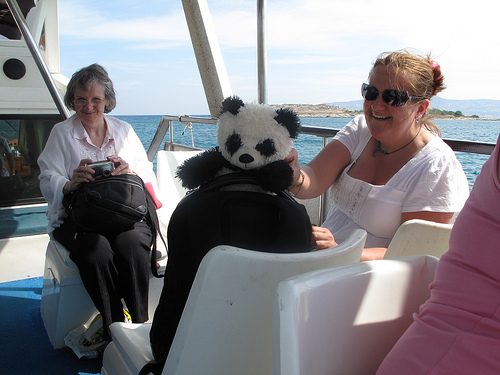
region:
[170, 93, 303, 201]
a panda plush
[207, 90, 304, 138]
ears of panda plush are black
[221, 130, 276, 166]
eyes and nose of panda plush are black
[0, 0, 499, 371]
women in a boat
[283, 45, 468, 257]
woman combs with a bun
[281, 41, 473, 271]
woman has white top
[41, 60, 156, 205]
woman has gray hair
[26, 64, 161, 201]
woman holds a camera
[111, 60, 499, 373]
people sits on white chairs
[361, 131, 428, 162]
necklace on neck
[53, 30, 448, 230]
two women on boat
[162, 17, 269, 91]
white rail on boat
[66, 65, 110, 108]
woman has grey hair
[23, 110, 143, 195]
woman has white shirt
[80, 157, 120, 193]
woman is holding camera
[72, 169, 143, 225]
woman is holding black bag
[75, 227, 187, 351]
woman has black pants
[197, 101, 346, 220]
woman holds panda doll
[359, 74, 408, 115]
woman is wearing sunglasses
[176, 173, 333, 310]
panda on black luggage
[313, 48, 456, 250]
a woman wearing white on a boat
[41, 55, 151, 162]
a woman wearing white on a boat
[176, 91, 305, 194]
a stuffed panda bear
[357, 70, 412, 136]
the face of a woman wearing sunglasses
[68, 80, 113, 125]
the face of a woman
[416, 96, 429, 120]
the ear of a woman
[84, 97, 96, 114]
the nose of a woman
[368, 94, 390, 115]
the nose of a woman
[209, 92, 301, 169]
the head of a stuffed panda's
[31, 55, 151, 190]
a woman holding a camera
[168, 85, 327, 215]
A panda bear on a woman's lap.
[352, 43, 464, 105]
A woman with brown hair.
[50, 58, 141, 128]
a woman with gray hair.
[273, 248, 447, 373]
a white seat on a boat.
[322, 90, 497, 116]
a small mountain range.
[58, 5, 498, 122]
a cloud filled blue sky.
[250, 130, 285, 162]
A black panda bear eye.;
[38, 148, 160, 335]
a woman holding a camera.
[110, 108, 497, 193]
A large body of water.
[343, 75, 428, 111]
a pair of black sun glasses.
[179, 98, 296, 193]
a soft panda toy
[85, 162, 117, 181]
a silver camera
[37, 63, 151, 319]
a woman holding a camera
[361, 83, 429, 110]
a pair of black sunglasses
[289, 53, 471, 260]
a woman wearing black sunglasses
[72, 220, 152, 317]
black trousers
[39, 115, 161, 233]
a white shirt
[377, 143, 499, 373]
a pink shirt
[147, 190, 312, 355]
a black bag on a white chair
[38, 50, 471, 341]
two women sitting on a boat